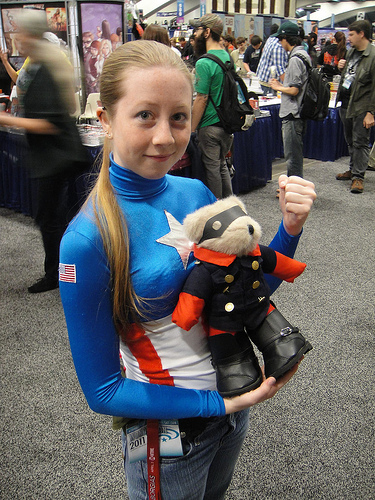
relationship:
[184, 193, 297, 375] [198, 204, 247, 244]
teddy bear wearing mask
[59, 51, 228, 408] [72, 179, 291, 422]
girl wearing shirt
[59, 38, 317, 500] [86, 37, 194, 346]
girl has hair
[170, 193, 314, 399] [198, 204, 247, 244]
teddy bear wearing mask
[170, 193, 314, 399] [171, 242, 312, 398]
teddy bear wearing clothes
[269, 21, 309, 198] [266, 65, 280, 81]
boy holding drink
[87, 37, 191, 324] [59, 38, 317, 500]
hair on girl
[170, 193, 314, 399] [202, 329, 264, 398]
teddy bear wearing boot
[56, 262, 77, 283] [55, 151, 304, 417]
flag attached to shirt